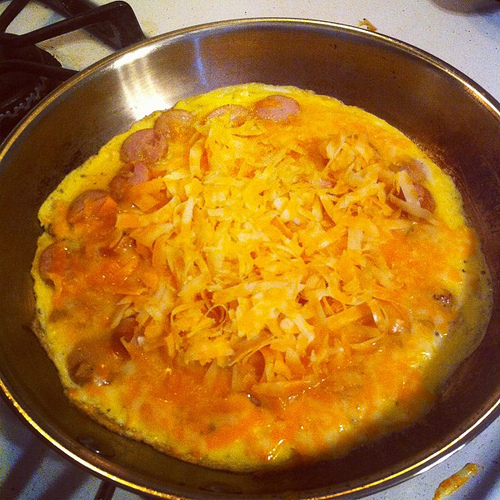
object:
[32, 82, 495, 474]
omelet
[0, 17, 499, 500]
pan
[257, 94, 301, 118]
sausage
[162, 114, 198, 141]
sausage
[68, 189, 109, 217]
sausage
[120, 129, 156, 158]
sausage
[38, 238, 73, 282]
sausage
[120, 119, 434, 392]
cheese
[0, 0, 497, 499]
stove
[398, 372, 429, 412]
yolk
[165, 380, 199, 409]
yolk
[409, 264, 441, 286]
yolk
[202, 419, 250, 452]
yolk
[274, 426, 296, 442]
yolk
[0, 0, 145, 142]
burner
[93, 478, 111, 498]
burner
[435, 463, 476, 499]
omelet part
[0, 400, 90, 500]
shadow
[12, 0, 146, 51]
edge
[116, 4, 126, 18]
part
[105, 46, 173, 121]
highlight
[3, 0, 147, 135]
support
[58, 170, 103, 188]
bubbles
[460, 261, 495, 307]
bubbles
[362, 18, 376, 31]
stain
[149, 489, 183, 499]
residue